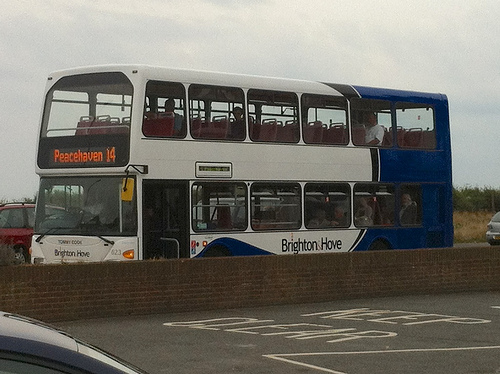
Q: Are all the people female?
A: No, they are both male and female.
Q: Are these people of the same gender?
A: No, they are both male and female.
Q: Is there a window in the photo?
A: Yes, there is a window.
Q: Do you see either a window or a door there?
A: Yes, there is a window.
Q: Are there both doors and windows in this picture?
A: Yes, there are both a window and a door.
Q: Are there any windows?
A: Yes, there is a window.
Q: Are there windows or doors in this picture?
A: Yes, there is a window.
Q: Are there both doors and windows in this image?
A: Yes, there are both a window and a door.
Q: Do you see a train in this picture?
A: No, there are no trains.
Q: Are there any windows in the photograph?
A: Yes, there is a window.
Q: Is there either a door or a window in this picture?
A: Yes, there is a window.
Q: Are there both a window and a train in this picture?
A: No, there is a window but no trains.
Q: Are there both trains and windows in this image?
A: No, there is a window but no trains.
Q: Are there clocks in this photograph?
A: No, there are no clocks.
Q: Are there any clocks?
A: No, there are no clocks.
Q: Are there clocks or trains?
A: No, there are no clocks or trains.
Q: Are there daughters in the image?
A: No, there are no daughters.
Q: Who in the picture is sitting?
A: The man is sitting.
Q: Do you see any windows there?
A: Yes, there is a window.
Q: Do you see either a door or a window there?
A: Yes, there is a window.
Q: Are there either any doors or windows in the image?
A: Yes, there is a window.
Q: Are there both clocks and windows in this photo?
A: No, there is a window but no clocks.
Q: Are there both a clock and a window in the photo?
A: No, there is a window but no clocks.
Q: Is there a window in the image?
A: Yes, there is a window.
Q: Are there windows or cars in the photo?
A: Yes, there is a window.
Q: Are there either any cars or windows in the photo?
A: Yes, there is a window.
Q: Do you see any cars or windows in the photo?
A: Yes, there is a window.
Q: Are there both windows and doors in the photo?
A: Yes, there are both a window and doors.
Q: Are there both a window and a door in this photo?
A: Yes, there are both a window and a door.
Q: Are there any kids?
A: No, there are no kids.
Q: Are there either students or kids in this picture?
A: No, there are no kids or students.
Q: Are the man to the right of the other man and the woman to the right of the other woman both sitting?
A: Yes, both the man and the woman are sitting.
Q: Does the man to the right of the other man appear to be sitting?
A: Yes, the man is sitting.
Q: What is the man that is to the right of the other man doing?
A: The man is sitting.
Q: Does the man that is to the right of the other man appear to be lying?
A: No, the man is sitting.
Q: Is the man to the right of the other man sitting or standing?
A: The man is sitting.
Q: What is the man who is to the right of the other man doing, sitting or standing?
A: The man is sitting.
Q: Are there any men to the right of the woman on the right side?
A: Yes, there is a man to the right of the woman.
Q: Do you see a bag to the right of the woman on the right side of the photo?
A: No, there is a man to the right of the woman.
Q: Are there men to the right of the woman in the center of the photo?
A: Yes, there is a man to the right of the woman.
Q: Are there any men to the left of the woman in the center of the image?
A: No, the man is to the right of the woman.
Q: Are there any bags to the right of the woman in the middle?
A: No, there is a man to the right of the woman.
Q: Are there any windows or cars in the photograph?
A: Yes, there is a window.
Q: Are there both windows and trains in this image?
A: No, there is a window but no trains.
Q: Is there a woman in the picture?
A: Yes, there is a woman.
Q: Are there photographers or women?
A: Yes, there is a woman.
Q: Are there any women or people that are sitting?
A: Yes, the woman is sitting.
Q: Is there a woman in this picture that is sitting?
A: Yes, there is a woman that is sitting.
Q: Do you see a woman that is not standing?
A: Yes, there is a woman that is sitting .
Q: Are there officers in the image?
A: No, there are no officers.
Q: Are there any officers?
A: No, there are no officers.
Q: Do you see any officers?
A: No, there are no officers.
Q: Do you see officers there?
A: No, there are no officers.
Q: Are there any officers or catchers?
A: No, there are no officers or catchers.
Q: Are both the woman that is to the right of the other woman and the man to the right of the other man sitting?
A: Yes, both the woman and the man are sitting.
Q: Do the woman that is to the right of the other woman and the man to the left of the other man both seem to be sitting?
A: Yes, both the woman and the man are sitting.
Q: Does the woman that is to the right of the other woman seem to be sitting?
A: Yes, the woman is sitting.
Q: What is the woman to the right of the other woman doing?
A: The woman is sitting.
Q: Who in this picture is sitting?
A: The woman is sitting.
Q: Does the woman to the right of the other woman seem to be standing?
A: No, the woman is sitting.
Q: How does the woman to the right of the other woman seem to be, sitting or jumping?
A: The woman is sitting.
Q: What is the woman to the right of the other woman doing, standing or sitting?
A: The woman is sitting.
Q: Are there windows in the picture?
A: Yes, there is a window.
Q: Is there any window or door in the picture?
A: Yes, there is a window.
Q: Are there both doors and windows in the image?
A: Yes, there are both a window and a door.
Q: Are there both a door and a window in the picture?
A: Yes, there are both a window and a door.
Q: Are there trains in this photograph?
A: No, there are no trains.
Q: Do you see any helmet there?
A: No, there are no helmets.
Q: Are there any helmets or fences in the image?
A: No, there are no helmets or fences.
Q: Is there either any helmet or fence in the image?
A: No, there are no helmets or fences.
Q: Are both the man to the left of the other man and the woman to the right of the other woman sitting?
A: Yes, both the man and the woman are sitting.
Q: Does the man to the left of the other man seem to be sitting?
A: Yes, the man is sitting.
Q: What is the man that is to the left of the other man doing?
A: The man is sitting.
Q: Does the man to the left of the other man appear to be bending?
A: No, the man is sitting.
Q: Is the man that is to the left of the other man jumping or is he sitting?
A: The man is sitting.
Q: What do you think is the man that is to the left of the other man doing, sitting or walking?
A: The man is sitting.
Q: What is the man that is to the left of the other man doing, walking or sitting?
A: The man is sitting.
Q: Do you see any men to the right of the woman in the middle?
A: Yes, there is a man to the right of the woman.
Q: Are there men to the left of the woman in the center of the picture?
A: No, the man is to the right of the woman.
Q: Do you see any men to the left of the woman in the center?
A: No, the man is to the right of the woman.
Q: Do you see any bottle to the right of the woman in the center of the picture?
A: No, there is a man to the right of the woman.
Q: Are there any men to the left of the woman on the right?
A: Yes, there is a man to the left of the woman.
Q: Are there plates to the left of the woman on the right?
A: No, there is a man to the left of the woman.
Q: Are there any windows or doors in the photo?
A: Yes, there is a window.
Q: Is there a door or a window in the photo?
A: Yes, there is a window.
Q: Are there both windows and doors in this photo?
A: Yes, there are both a window and a door.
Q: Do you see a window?
A: Yes, there is a window.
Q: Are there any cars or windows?
A: Yes, there is a window.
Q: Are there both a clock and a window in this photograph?
A: No, there is a window but no clocks.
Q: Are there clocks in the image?
A: No, there are no clocks.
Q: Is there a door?
A: Yes, there is a door.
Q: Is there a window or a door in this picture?
A: Yes, there is a door.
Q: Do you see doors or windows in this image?
A: Yes, there is a door.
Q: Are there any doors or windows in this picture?
A: Yes, there is a door.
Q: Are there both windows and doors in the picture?
A: Yes, there are both a door and windows.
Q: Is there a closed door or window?
A: Yes, there is a closed door.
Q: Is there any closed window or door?
A: Yes, there is a closed door.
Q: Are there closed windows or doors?
A: Yes, there is a closed door.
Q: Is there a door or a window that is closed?
A: Yes, the door is closed.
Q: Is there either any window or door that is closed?
A: Yes, the door is closed.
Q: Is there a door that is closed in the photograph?
A: Yes, there is a closed door.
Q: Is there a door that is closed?
A: Yes, there is a door that is closed.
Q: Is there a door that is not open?
A: Yes, there is an closed door.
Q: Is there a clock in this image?
A: No, there are no clocks.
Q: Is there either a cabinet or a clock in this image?
A: No, there are no clocks or cabinets.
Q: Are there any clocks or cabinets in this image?
A: No, there are no clocks or cabinets.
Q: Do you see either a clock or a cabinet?
A: No, there are no clocks or cabinets.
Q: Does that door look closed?
A: Yes, the door is closed.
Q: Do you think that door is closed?
A: Yes, the door is closed.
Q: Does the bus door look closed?
A: Yes, the door is closed.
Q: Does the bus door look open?
A: No, the door is closed.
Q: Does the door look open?
A: No, the door is closed.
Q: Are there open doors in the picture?
A: No, there is a door but it is closed.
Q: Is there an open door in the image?
A: No, there is a door but it is closed.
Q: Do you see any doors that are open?
A: No, there is a door but it is closed.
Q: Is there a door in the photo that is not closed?
A: No, there is a door but it is closed.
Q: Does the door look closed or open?
A: The door is closed.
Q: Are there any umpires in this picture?
A: No, there are no umpires.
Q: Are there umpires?
A: No, there are no umpires.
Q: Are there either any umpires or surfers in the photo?
A: No, there are no umpires or surfers.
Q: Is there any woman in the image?
A: Yes, there is a woman.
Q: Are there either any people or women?
A: Yes, there is a woman.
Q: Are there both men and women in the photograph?
A: Yes, there are both a woman and a man.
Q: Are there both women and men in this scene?
A: Yes, there are both a woman and a man.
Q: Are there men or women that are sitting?
A: Yes, the woman is sitting.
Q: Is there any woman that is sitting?
A: Yes, there is a woman that is sitting.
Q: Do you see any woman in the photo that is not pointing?
A: Yes, there is a woman that is sitting .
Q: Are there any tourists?
A: No, there are no tourists.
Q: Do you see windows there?
A: Yes, there is a window.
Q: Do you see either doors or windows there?
A: Yes, there is a window.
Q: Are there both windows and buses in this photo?
A: Yes, there are both a window and a bus.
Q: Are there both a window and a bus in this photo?
A: Yes, there are both a window and a bus.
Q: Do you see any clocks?
A: No, there are no clocks.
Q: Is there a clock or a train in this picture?
A: No, there are no clocks or trains.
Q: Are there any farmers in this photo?
A: No, there are no farmers.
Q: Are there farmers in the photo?
A: No, there are no farmers.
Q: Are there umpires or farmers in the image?
A: No, there are no farmers or umpires.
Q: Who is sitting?
A: The man is sitting.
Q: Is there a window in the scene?
A: Yes, there is a window.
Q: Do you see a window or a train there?
A: Yes, there is a window.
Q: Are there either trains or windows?
A: Yes, there is a window.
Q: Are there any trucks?
A: No, there are no trucks.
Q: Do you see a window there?
A: Yes, there is a window.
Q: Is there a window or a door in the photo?
A: Yes, there is a window.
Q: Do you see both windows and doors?
A: Yes, there are both a window and a door.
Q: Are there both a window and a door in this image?
A: Yes, there are both a window and a door.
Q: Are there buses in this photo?
A: Yes, there is a bus.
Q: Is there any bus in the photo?
A: Yes, there is a bus.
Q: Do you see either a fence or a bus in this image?
A: Yes, there is a bus.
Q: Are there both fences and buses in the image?
A: No, there is a bus but no fences.